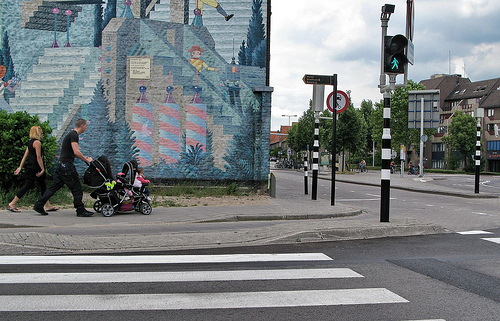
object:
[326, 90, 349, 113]
sign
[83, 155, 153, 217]
baby stroller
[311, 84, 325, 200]
pole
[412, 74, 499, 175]
building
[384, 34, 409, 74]
light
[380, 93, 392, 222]
pole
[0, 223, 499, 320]
tarmac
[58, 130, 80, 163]
shirt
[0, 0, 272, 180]
wall mural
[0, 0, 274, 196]
building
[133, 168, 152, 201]
child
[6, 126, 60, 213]
woman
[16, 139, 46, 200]
black clothes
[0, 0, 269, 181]
mural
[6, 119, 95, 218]
couple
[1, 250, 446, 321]
stripes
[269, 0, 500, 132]
sky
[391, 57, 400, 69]
person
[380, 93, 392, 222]
poles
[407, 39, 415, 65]
sign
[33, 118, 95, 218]
man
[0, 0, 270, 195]
wall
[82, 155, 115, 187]
hood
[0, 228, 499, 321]
road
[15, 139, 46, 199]
clothes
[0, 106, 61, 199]
tree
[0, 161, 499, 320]
street